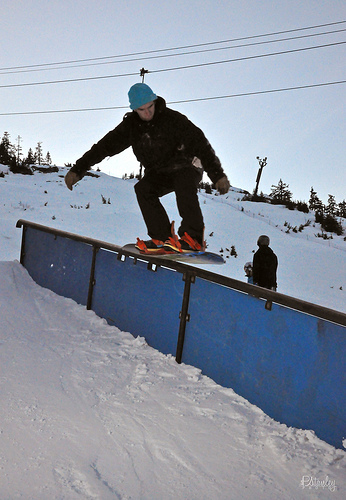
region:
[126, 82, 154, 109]
a green knit cap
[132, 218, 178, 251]
an orange snowboard boot strap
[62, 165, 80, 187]
brown ski gloves on the snowboarder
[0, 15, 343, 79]
the ski lift chair cable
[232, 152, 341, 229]
trees lining the slope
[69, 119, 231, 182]
dark brown ski jacket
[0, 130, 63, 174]
pine trees towards the top of the hill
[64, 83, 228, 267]
the snowboarder performing a trick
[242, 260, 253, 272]
a skier with a grey ski helmet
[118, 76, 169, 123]
head of a person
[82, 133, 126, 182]
arm of a person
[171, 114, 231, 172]
arm of a person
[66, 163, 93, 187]
hand of a person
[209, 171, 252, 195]
hand of a person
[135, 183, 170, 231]
leg of a person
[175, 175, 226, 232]
leg of a person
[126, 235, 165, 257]
feet of a person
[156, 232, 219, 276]
feet of a person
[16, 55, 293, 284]
a snowboarder riding a rail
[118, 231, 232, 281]
a snowboard on a rail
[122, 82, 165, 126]
the head of a man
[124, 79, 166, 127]
a man wearing a blue cap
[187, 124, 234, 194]
the arm of a man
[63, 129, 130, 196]
the arm of a man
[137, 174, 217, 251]
the legs of a man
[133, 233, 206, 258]
two orange and black snowboarding boots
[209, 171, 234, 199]
a tan ski glove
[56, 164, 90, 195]
a tan ski glove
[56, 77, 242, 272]
A snowboarder doing a rail trick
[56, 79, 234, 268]
A snowboarder doing a rail trick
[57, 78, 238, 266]
A snowboarder doing a rail trick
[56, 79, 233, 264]
A snowboarder doing a rail trick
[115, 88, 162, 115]
boy has blue hat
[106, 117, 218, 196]
boy has black coat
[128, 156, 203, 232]
boy has black pants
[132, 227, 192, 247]
black and orange boots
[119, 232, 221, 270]
boy on white board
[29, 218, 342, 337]
grey rail on fence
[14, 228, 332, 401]
blue fence under rails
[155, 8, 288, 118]
sky is blue and grey